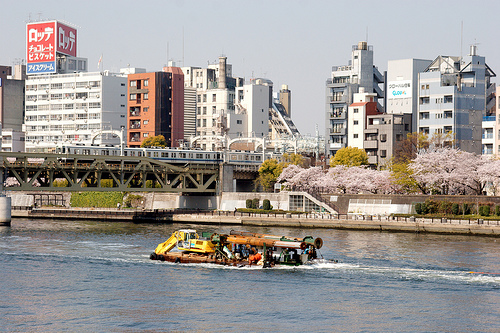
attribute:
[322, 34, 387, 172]
building — white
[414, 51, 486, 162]
building — white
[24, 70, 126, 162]
building — white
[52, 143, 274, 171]
train — passenger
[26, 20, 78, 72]
sign — huge, red, blue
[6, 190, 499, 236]
wall — concrete, sea wall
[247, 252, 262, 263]
object — orange, large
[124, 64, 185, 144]
building — different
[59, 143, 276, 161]
train — passenger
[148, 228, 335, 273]
boat — large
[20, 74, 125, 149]
building — white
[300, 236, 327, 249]
pipe end — green